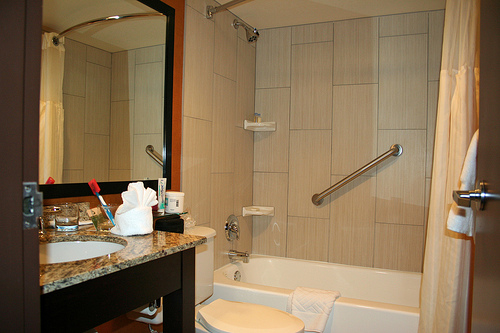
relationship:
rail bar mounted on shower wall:
[310, 142, 404, 207] [251, 11, 446, 276]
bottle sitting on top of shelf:
[251, 111, 260, 124] [241, 118, 276, 133]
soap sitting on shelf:
[250, 206, 260, 212] [241, 204, 275, 218]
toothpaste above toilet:
[155, 174, 167, 215] [126, 223, 305, 332]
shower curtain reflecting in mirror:
[38, 26, 64, 185] [38, 0, 166, 184]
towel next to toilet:
[289, 284, 340, 332] [126, 223, 305, 332]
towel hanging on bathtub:
[289, 284, 340, 332] [198, 250, 421, 332]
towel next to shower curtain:
[289, 284, 340, 332] [416, 0, 478, 333]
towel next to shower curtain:
[445, 125, 478, 237] [416, 0, 478, 333]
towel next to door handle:
[445, 125, 478, 237] [449, 177, 486, 209]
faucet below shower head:
[229, 244, 252, 264] [231, 17, 258, 43]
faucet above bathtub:
[229, 244, 252, 264] [198, 250, 421, 332]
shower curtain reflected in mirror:
[38, 26, 64, 185] [38, 0, 166, 184]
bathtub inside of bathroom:
[198, 250, 421, 332] [36, 0, 499, 333]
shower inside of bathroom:
[179, 0, 445, 333] [36, 0, 499, 333]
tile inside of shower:
[181, 0, 446, 272] [179, 0, 445, 333]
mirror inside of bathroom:
[38, 0, 166, 184] [36, 0, 499, 333]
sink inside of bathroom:
[40, 231, 127, 267] [36, 0, 499, 333]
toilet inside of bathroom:
[126, 223, 305, 332] [36, 0, 499, 333]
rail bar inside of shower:
[310, 142, 404, 207] [179, 0, 445, 333]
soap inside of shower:
[250, 206, 260, 212] [179, 0, 445, 333]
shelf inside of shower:
[241, 204, 275, 218] [179, 0, 445, 333]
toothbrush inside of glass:
[88, 174, 115, 222] [96, 200, 120, 229]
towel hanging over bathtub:
[289, 284, 340, 332] [198, 250, 421, 332]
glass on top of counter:
[53, 198, 80, 231] [37, 215, 205, 299]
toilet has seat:
[126, 223, 305, 332] [199, 294, 304, 332]